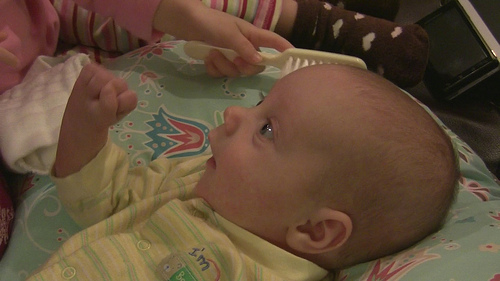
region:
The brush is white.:
[180, 23, 375, 88]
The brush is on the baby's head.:
[175, 30, 375, 88]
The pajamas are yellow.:
[56, 142, 290, 278]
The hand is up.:
[63, 52, 135, 146]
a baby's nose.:
[215, 105, 245, 135]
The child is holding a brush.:
[5, 3, 435, 88]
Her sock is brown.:
[273, 2, 428, 72]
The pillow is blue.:
[83, 45, 468, 277]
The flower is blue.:
[136, 105, 214, 162]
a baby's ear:
[278, 203, 356, 259]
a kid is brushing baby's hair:
[147, 15, 390, 117]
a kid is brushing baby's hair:
[191, 4, 451, 269]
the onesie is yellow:
[23, 31, 439, 278]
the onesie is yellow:
[38, 105, 291, 277]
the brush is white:
[181, 21, 404, 106]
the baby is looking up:
[148, 58, 350, 203]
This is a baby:
[26, 56, 460, 272]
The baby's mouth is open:
[186, 120, 234, 179]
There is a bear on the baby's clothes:
[147, 246, 191, 279]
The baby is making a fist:
[65, 60, 138, 126]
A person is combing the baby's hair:
[6, 3, 376, 76]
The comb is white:
[185, 22, 377, 81]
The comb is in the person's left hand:
[193, 7, 376, 81]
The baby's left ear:
[267, 186, 367, 266]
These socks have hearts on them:
[290, 1, 458, 67]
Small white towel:
[2, 58, 95, 166]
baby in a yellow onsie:
[49, 61, 492, 275]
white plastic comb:
[181, 30, 383, 75]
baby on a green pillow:
[16, 42, 457, 278]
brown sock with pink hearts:
[292, 0, 431, 86]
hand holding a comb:
[139, 0, 374, 75]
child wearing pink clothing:
[4, 0, 453, 82]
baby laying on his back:
[26, 60, 462, 275]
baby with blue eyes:
[45, 49, 441, 279]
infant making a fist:
[12, 52, 492, 279]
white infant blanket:
[1, 50, 119, 170]